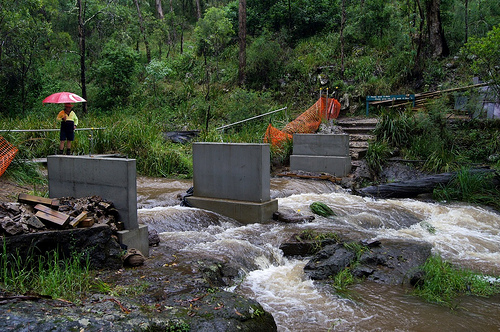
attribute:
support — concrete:
[291, 133, 356, 176]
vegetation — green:
[8, 10, 295, 160]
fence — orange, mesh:
[282, 104, 333, 132]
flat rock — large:
[87, 247, 264, 329]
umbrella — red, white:
[41, 90, 85, 105]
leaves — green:
[177, 60, 241, 93]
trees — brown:
[193, 2, 255, 126]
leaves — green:
[16, 8, 322, 76]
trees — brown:
[3, 1, 498, 111]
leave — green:
[377, 35, 413, 65]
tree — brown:
[6, 0, 468, 180]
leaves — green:
[248, 34, 280, 58]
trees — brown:
[178, 23, 292, 100]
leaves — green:
[158, 31, 235, 78]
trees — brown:
[32, 27, 336, 119]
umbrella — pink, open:
[44, 90, 92, 109]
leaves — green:
[205, 25, 221, 46]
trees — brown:
[54, 11, 384, 123]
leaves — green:
[260, 4, 328, 51]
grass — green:
[408, 251, 481, 307]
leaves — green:
[289, 40, 399, 88]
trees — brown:
[6, 3, 480, 198]